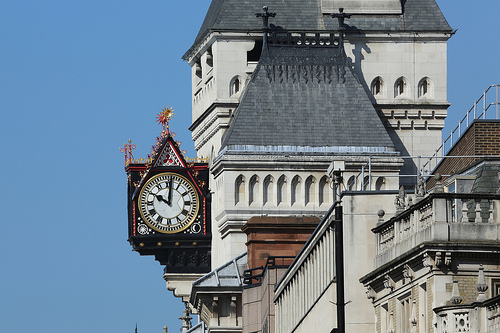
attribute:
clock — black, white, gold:
[136, 171, 204, 231]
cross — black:
[252, 1, 279, 41]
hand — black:
[165, 174, 175, 209]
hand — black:
[154, 190, 170, 206]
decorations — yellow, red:
[154, 100, 174, 133]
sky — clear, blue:
[16, 69, 87, 142]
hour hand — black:
[144, 189, 167, 210]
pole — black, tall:
[320, 199, 349, 326]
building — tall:
[192, 58, 471, 307]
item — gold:
[149, 98, 183, 127]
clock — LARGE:
[117, 101, 211, 252]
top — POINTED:
[137, 103, 187, 162]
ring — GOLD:
[137, 171, 199, 231]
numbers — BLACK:
[145, 177, 195, 226]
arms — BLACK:
[154, 180, 179, 208]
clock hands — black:
[118, 155, 238, 275]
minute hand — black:
[157, 166, 180, 205]